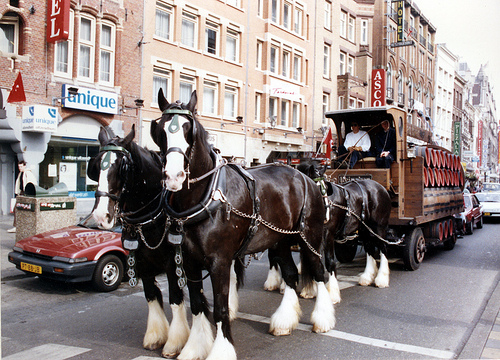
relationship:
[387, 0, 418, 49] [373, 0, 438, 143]
sign on building